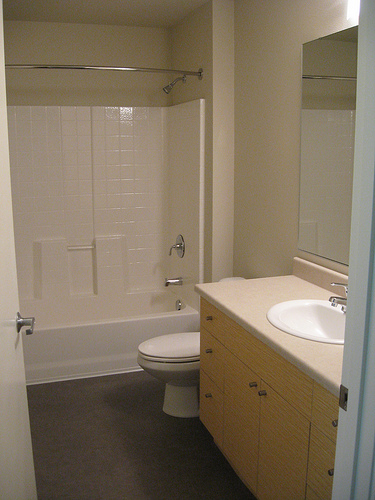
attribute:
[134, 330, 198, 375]
toilet lid — CLOSED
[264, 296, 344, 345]
sink — clean, white, bathroom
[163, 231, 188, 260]
shower knob — silver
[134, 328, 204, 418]
toilet — white, bathroom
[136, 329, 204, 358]
toilet lid — down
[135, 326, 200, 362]
toilet seat — down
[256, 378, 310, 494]
door — brown, cabinet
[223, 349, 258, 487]
door — cabinet, brown